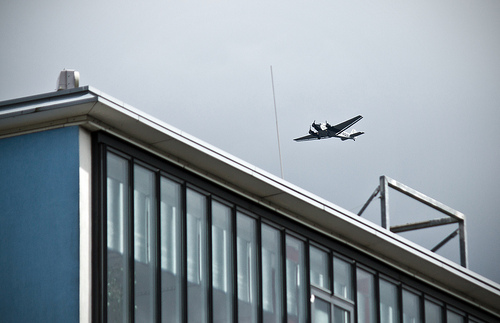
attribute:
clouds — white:
[136, 23, 393, 95]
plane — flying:
[288, 107, 375, 146]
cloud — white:
[6, 4, 498, 274]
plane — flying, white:
[293, 112, 366, 142]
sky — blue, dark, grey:
[14, 1, 474, 291]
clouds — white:
[135, 18, 247, 81]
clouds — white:
[181, 17, 262, 67]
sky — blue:
[294, 6, 411, 58]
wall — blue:
[3, 84, 120, 321]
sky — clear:
[204, 22, 463, 60]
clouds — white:
[255, 52, 372, 104]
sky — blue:
[25, 19, 475, 232]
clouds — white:
[300, 4, 499, 112]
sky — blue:
[0, 2, 497, 232]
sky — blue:
[6, 5, 498, 119]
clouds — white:
[334, 25, 433, 94]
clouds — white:
[295, 23, 427, 83]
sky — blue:
[2, 3, 498, 210]